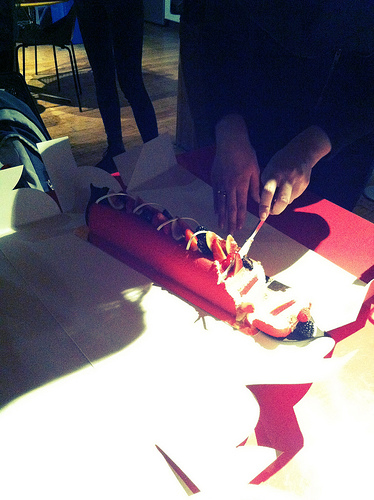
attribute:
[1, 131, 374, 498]
box — white, cardboard, unfolded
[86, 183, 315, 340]
cake — cylinder, decorated, long, cylindrical, slender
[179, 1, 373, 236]
person — cutting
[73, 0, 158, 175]
person — standing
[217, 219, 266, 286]
knife — stainless steel, cutting, silver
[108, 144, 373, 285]
table — red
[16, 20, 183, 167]
floor — wooden, brown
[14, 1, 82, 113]
chair — dark